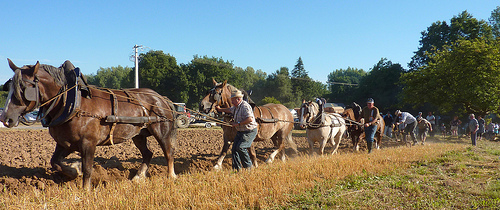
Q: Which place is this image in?
A: It is at the field.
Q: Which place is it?
A: It is a field.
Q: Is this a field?
A: Yes, it is a field.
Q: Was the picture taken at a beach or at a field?
A: It was taken at a field.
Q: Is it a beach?
A: No, it is a field.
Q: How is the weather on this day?
A: It is clear.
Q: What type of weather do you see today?
A: It is clear.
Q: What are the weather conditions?
A: It is clear.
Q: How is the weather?
A: It is clear.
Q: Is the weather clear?
A: Yes, it is clear.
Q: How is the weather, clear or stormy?
A: It is clear.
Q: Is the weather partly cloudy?
A: No, it is clear.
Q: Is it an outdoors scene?
A: Yes, it is outdoors.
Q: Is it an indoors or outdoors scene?
A: It is outdoors.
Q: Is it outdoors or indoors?
A: It is outdoors.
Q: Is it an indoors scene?
A: No, it is outdoors.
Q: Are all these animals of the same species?
A: Yes, all the animals are horses.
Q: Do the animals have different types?
A: No, all the animals are horses.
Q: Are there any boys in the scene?
A: No, there are no boys.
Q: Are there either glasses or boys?
A: No, there are no boys or glasses.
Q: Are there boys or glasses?
A: No, there are no boys or glasses.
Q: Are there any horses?
A: Yes, there is a horse.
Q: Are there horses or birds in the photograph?
A: Yes, there is a horse.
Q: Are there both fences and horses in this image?
A: No, there is a horse but no fences.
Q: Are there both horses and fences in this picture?
A: No, there is a horse but no fences.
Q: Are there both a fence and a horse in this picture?
A: No, there is a horse but no fences.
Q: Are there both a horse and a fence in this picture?
A: No, there is a horse but no fences.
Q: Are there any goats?
A: No, there are no goats.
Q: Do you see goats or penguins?
A: No, there are no goats or penguins.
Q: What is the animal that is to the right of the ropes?
A: The animal is a horse.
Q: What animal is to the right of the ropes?
A: The animal is a horse.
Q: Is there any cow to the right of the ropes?
A: No, there is a horse to the right of the ropes.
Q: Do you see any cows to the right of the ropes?
A: No, there is a horse to the right of the ropes.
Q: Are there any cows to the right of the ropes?
A: No, there is a horse to the right of the ropes.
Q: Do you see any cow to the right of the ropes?
A: No, there is a horse to the right of the ropes.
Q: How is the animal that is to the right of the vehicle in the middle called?
A: The animal is a horse.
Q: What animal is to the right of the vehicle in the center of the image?
A: The animal is a horse.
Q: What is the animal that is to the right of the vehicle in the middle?
A: The animal is a horse.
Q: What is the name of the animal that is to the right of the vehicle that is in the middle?
A: The animal is a horse.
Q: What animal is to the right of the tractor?
A: The animal is a horse.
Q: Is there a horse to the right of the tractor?
A: Yes, there is a horse to the right of the tractor.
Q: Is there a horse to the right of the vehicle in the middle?
A: Yes, there is a horse to the right of the tractor.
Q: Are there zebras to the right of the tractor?
A: No, there is a horse to the right of the tractor.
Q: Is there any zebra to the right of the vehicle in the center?
A: No, there is a horse to the right of the tractor.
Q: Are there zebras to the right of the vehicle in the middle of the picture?
A: No, there is a horse to the right of the tractor.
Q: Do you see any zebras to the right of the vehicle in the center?
A: No, there is a horse to the right of the tractor.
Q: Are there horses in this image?
A: Yes, there are horses.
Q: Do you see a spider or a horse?
A: Yes, there are horses.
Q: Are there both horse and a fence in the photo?
A: No, there are horses but no fences.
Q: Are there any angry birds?
A: No, there are no angry birds.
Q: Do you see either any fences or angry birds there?
A: No, there are no angry birds or fences.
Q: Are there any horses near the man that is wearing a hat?
A: Yes, there are horses near the man.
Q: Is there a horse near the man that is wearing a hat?
A: Yes, there are horses near the man.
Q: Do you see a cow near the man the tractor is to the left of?
A: No, there are horses near the man.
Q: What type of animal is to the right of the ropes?
A: The animals are horses.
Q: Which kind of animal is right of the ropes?
A: The animals are horses.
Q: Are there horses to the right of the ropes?
A: Yes, there are horses to the right of the ropes.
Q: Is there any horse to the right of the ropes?
A: Yes, there are horses to the right of the ropes.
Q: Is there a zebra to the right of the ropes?
A: No, there are horses to the right of the ropes.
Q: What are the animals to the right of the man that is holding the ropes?
A: The animals are horses.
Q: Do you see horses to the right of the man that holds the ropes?
A: Yes, there are horses to the right of the man.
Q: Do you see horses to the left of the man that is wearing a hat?
A: No, the horses are to the right of the man.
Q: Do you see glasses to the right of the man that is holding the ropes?
A: No, there are horses to the right of the man.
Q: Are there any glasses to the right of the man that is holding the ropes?
A: No, there are horses to the right of the man.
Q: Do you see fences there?
A: No, there are no fences.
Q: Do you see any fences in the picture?
A: No, there are no fences.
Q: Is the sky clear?
A: Yes, the sky is clear.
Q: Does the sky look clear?
A: Yes, the sky is clear.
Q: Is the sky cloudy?
A: No, the sky is clear.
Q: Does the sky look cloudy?
A: No, the sky is clear.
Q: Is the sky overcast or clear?
A: The sky is clear.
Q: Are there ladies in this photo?
A: No, there are no ladies.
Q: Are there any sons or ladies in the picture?
A: No, there are no ladies or sons.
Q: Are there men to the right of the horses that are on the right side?
A: Yes, there is a man to the right of the horses.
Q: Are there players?
A: No, there are no players.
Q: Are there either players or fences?
A: No, there are no players or fences.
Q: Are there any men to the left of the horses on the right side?
A: Yes, there is a man to the left of the horses.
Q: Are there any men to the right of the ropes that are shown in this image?
A: Yes, there is a man to the right of the ropes.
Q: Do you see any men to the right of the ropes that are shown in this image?
A: Yes, there is a man to the right of the ropes.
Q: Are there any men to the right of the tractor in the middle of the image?
A: Yes, there is a man to the right of the tractor.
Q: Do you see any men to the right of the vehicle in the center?
A: Yes, there is a man to the right of the tractor.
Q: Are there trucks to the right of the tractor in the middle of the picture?
A: No, there is a man to the right of the tractor.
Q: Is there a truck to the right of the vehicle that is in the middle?
A: No, there is a man to the right of the tractor.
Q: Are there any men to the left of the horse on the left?
A: No, the man is to the right of the horse.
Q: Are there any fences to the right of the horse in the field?
A: No, there is a man to the right of the horse.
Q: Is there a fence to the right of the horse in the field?
A: No, there is a man to the right of the horse.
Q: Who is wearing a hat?
A: The man is wearing a hat.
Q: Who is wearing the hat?
A: The man is wearing a hat.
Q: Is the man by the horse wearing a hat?
A: Yes, the man is wearing a hat.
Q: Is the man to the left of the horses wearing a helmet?
A: No, the man is wearing a hat.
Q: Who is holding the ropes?
A: The man is holding the ropes.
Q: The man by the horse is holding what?
A: The man is holding the ropes.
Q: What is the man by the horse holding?
A: The man is holding the ropes.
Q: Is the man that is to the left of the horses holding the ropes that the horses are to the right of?
A: Yes, the man is holding the ropes.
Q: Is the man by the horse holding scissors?
A: No, the man is holding the ropes.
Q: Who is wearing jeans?
A: The man is wearing jeans.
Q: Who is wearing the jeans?
A: The man is wearing jeans.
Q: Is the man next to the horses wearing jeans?
A: Yes, the man is wearing jeans.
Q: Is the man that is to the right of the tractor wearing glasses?
A: No, the man is wearing jeans.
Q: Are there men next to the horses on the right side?
A: Yes, there is a man next to the horses.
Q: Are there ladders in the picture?
A: No, there are no ladders.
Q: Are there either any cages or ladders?
A: No, there are no ladders or cages.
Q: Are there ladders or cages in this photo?
A: No, there are no ladders or cages.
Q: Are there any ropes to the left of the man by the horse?
A: Yes, there are ropes to the left of the man.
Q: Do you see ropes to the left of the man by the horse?
A: Yes, there are ropes to the left of the man.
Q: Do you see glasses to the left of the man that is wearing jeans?
A: No, there are ropes to the left of the man.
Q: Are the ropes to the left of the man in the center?
A: Yes, the ropes are to the left of the man.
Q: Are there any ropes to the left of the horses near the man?
A: Yes, there are ropes to the left of the horses.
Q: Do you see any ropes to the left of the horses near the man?
A: Yes, there are ropes to the left of the horses.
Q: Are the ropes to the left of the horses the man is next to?
A: Yes, the ropes are to the left of the horses.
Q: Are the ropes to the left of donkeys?
A: No, the ropes are to the left of the horses.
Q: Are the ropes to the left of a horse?
A: Yes, the ropes are to the left of a horse.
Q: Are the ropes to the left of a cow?
A: No, the ropes are to the left of a horse.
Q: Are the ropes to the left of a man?
A: Yes, the ropes are to the left of a man.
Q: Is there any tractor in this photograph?
A: Yes, there is a tractor.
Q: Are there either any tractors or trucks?
A: Yes, there is a tractor.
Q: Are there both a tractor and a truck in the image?
A: No, there is a tractor but no trucks.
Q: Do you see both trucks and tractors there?
A: No, there is a tractor but no trucks.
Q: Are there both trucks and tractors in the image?
A: No, there is a tractor but no trucks.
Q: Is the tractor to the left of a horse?
A: Yes, the tractor is to the left of a horse.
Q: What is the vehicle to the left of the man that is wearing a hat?
A: The vehicle is a tractor.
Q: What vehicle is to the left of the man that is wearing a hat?
A: The vehicle is a tractor.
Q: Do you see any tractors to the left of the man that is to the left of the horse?
A: Yes, there is a tractor to the left of the man.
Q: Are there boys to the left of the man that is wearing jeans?
A: No, there is a tractor to the left of the man.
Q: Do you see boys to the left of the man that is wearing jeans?
A: No, there is a tractor to the left of the man.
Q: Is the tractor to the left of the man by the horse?
A: Yes, the tractor is to the left of the man.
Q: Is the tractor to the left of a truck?
A: No, the tractor is to the left of the man.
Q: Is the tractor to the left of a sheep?
A: No, the tractor is to the left of the horse.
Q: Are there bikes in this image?
A: No, there are no bikes.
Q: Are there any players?
A: No, there are no players.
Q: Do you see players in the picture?
A: No, there are no players.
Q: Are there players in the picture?
A: No, there are no players.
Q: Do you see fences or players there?
A: No, there are no players or fences.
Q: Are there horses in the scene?
A: Yes, there is a horse.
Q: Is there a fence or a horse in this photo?
A: Yes, there is a horse.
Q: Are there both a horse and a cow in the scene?
A: No, there is a horse but no cows.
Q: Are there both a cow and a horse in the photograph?
A: No, there is a horse but no cows.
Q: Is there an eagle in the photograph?
A: No, there are no eagles.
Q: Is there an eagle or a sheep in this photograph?
A: No, there are no eagles or sheep.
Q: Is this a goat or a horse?
A: This is a horse.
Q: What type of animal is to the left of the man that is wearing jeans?
A: The animal is a horse.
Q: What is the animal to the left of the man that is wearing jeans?
A: The animal is a horse.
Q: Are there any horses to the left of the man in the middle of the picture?
A: Yes, there is a horse to the left of the man.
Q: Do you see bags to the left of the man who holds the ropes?
A: No, there is a horse to the left of the man.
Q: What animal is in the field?
A: The horse is in the field.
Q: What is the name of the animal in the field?
A: The animal is a horse.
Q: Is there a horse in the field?
A: Yes, there is a horse in the field.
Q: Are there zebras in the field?
A: No, there is a horse in the field.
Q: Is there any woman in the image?
A: No, there are no women.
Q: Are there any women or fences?
A: No, there are no women or fences.